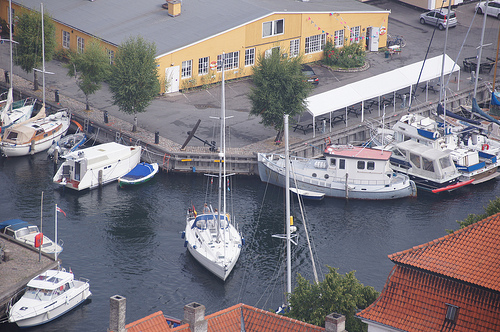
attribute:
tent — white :
[294, 48, 464, 120]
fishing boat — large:
[257, 117, 418, 224]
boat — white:
[256, 148, 417, 202]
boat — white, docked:
[5, 262, 112, 329]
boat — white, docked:
[0, 207, 71, 262]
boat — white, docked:
[254, 135, 420, 206]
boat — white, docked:
[119, 160, 159, 192]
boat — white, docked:
[49, 138, 146, 195]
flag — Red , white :
[51, 197, 70, 219]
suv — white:
[414, 4, 461, 32]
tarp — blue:
[126, 157, 153, 178]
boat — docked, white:
[0, 90, 89, 153]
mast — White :
[216, 60, 231, 240]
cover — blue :
[122, 161, 153, 176]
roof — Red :
[331, 144, 390, 164]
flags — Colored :
[305, 11, 386, 42]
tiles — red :
[398, 289, 423, 309]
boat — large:
[251, 136, 446, 243]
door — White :
[163, 66, 183, 94]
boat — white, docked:
[361, 103, 471, 202]